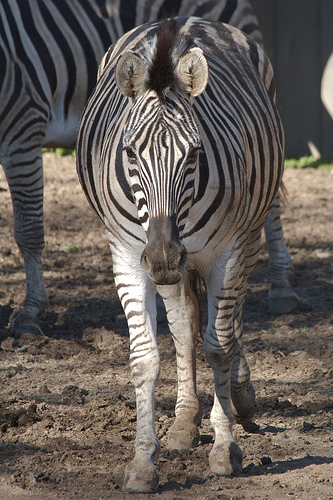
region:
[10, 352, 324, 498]
ground is grey and muddy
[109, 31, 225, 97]
black mane between tan hairy ears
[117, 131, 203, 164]
curved and bumpy lines between eyes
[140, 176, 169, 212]
straight lines on top of nose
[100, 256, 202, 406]
paler stripes over legs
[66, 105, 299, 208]
bulging on both sides of body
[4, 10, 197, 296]
zebra near another zebra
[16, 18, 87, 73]
thin tan lines between white stripes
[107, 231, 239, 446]
back leg between two front legs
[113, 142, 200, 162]
black eyes above curved black stripes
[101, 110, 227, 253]
black and white rings of body encircling head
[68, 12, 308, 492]
The zebra's stripes are black.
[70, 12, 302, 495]
The zebra's stripes are white.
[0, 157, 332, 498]
The zebra is standing in a muddy area.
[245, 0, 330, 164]
There's a wooden fences in the background.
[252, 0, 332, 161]
The fence is constructed from wide boards.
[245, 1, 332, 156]
The fence is gray.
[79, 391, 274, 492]
The zebra's hooves are muddy.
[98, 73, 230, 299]
The zebra if facing forward.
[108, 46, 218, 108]
The zebra's ears are pointed upward.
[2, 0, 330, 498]
Zebras are not in their natural habitat.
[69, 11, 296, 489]
a zebra walking towards the camera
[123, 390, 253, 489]
the zebra has muddy hooves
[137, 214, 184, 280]
the zebra has a black nose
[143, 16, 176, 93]
the zebra has a black mane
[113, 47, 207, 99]
the zebra's ears are facing forward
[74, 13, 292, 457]
the zebra has an unique black and white stripe pattern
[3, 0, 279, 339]
a zebra is behind the walking zebra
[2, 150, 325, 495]
the ground is muddy and dusty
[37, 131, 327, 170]
green grass is behind the zebras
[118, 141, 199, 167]
the eyes are black on the zebra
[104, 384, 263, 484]
Zebra walking in the dirt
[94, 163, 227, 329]
Zebra looking towards the camera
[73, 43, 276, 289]
Black and white zebra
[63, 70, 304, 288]
Zebra at the zoo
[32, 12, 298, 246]
Lots of zebras at the zoo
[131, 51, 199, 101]
Zebra mane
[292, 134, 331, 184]
There is grass in the back of the enclosure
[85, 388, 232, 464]
Most of the zebra's enclosure is muddy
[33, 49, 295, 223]
A zebra on exhibit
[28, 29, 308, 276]
A large zebra